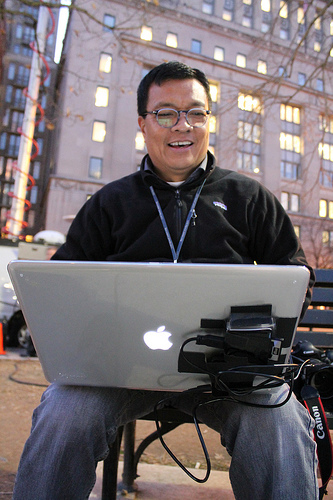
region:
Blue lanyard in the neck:
[121, 147, 227, 268]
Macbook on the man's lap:
[17, 236, 299, 399]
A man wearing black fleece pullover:
[41, 31, 298, 264]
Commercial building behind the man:
[58, 9, 332, 129]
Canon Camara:
[274, 323, 332, 380]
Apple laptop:
[2, 245, 296, 408]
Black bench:
[269, 213, 332, 356]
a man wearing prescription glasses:
[129, 79, 218, 147]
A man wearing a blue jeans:
[15, 335, 312, 481]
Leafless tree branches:
[69, 0, 325, 77]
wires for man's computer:
[160, 317, 322, 420]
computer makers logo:
[131, 312, 183, 363]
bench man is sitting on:
[291, 290, 328, 357]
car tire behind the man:
[5, 303, 24, 362]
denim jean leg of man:
[36, 395, 108, 497]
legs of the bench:
[106, 421, 147, 498]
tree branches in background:
[221, 69, 322, 157]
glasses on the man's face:
[127, 103, 213, 139]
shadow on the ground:
[151, 473, 222, 499]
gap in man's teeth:
[170, 137, 181, 145]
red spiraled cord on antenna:
[14, 18, 48, 239]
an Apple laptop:
[7, 256, 314, 402]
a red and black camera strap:
[301, 395, 331, 456]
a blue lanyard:
[142, 165, 215, 267]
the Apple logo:
[138, 313, 177, 356]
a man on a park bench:
[11, 55, 317, 493]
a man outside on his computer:
[6, 33, 323, 487]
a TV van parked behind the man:
[1, 231, 67, 356]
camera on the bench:
[289, 338, 331, 486]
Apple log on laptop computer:
[131, 323, 170, 353]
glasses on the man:
[148, 104, 207, 123]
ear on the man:
[134, 115, 146, 133]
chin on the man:
[166, 157, 200, 166]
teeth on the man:
[165, 139, 194, 145]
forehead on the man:
[165, 88, 195, 96]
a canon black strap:
[299, 389, 330, 468]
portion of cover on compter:
[44, 295, 153, 320]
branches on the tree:
[289, 34, 331, 84]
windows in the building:
[90, 84, 109, 145]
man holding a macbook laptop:
[19, 35, 310, 432]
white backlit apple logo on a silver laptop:
[133, 317, 179, 366]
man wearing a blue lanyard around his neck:
[127, 55, 231, 257]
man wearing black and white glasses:
[128, 48, 219, 185]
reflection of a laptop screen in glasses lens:
[151, 106, 180, 133]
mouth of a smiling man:
[153, 129, 209, 163]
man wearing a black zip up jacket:
[49, 55, 299, 294]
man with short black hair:
[119, 41, 216, 201]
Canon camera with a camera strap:
[270, 320, 332, 468]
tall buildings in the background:
[6, 3, 111, 211]